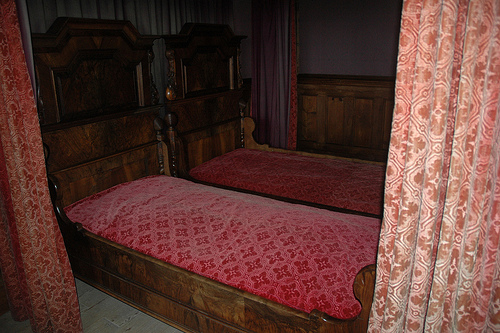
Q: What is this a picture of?
A: A bed.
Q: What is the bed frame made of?
A: Wood.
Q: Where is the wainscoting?
A: Back wall.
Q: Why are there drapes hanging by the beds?
A: To block the light.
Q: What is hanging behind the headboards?
A: Drapes.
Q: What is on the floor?
A: Tile.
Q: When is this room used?
A: Bedtime.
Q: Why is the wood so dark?
A: Better for sleep.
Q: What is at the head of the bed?
A: Its the headboard.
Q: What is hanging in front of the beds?
A: Two curtains.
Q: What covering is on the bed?
A: A red bedspread.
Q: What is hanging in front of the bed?
A: Curtains.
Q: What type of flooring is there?
A: White tile.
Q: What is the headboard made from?
A: Wood.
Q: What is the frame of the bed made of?
A: Wood.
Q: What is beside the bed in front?
A: Another bed.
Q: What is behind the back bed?
A: Wooden paneling.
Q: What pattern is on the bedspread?
A: A star pattern.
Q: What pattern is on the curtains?
A: A star pattern.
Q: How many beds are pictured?
A: 2.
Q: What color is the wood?
A: Brown.